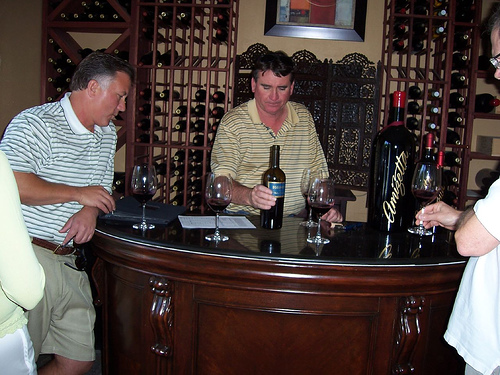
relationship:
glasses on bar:
[286, 176, 377, 253] [181, 226, 495, 286]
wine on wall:
[262, 144, 286, 234] [1, 1, 497, 235]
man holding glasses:
[415, 174, 499, 372] [405, 161, 446, 237]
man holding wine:
[411, 11, 497, 373] [206, 20, 235, 48]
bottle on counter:
[365, 91, 415, 241] [60, 173, 499, 285]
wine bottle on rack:
[209, 88, 230, 104] [140, 11, 232, 208]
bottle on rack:
[156, 47, 181, 69] [123, 0, 240, 216]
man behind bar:
[206, 51, 345, 223] [84, 200, 471, 373]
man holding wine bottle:
[206, 51, 345, 223] [261, 146, 285, 230]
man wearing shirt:
[20, 190, 137, 204] [0, 90, 120, 246]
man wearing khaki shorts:
[20, 190, 137, 204] [9, 243, 139, 358]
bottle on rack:
[396, 21, 439, 47] [375, 0, 499, 205]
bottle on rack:
[423, 88, 441, 98] [369, 4, 478, 215]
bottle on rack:
[450, 72, 469, 89] [369, 4, 478, 215]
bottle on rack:
[394, 23, 409, 35] [369, 4, 478, 215]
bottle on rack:
[423, 88, 441, 98] [359, 2, 499, 223]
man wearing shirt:
[0, 50, 139, 375] [0, 92, 118, 245]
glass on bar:
[123, 139, 183, 261] [84, 200, 471, 373]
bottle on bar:
[365, 91, 415, 241] [21, 95, 490, 288]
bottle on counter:
[365, 91, 415, 241] [110, 190, 491, 255]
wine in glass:
[313, 200, 331, 217] [309, 179, 335, 243]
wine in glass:
[207, 196, 230, 210] [202, 170, 235, 243]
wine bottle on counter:
[212, 90, 228, 103] [93, 195, 470, 272]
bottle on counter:
[365, 91, 415, 241] [93, 195, 470, 272]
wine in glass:
[410, 188, 440, 206] [308, 173, 334, 245]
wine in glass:
[205, 198, 232, 211] [131, 164, 158, 234]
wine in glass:
[259, 141, 288, 233] [299, 166, 321, 228]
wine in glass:
[410, 188, 440, 206] [414, 166, 439, 241]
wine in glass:
[410, 188, 440, 206] [407, 160, 439, 235]